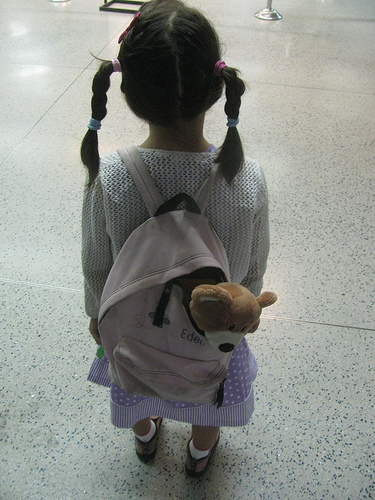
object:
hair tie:
[213, 60, 227, 78]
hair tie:
[226, 116, 240, 127]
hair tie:
[109, 58, 123, 71]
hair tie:
[87, 117, 103, 131]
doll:
[189, 281, 278, 354]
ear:
[190, 284, 233, 307]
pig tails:
[214, 60, 252, 187]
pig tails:
[80, 49, 122, 192]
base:
[254, 7, 282, 21]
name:
[181, 328, 205, 346]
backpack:
[98, 143, 232, 410]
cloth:
[86, 336, 259, 430]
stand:
[255, 1, 282, 26]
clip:
[117, 10, 141, 46]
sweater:
[80, 152, 271, 320]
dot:
[234, 376, 237, 380]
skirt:
[83, 333, 259, 428]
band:
[87, 117, 102, 131]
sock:
[189, 439, 211, 462]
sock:
[133, 417, 157, 442]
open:
[170, 256, 278, 374]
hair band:
[213, 58, 228, 79]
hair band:
[111, 58, 122, 73]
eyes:
[228, 320, 247, 332]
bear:
[189, 280, 278, 370]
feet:
[132, 412, 222, 476]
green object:
[95, 346, 104, 359]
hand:
[89, 317, 102, 346]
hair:
[79, 0, 252, 193]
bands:
[214, 57, 240, 129]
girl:
[77, 0, 279, 478]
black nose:
[218, 342, 235, 353]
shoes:
[129, 417, 222, 479]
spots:
[227, 369, 246, 404]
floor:
[0, 0, 375, 500]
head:
[187, 280, 278, 356]